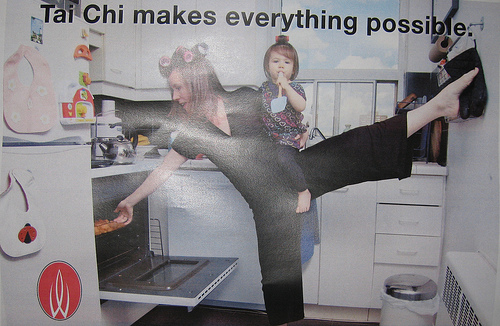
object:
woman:
[113, 42, 478, 326]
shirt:
[170, 87, 318, 213]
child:
[257, 36, 312, 213]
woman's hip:
[245, 150, 319, 209]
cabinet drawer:
[376, 174, 445, 205]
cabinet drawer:
[373, 202, 443, 237]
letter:
[40, 4, 56, 23]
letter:
[53, 9, 66, 23]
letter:
[69, 4, 74, 22]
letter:
[83, 4, 101, 24]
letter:
[103, 5, 116, 23]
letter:
[133, 10, 154, 24]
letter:
[157, 10, 171, 24]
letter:
[173, 5, 186, 24]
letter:
[188, 10, 201, 25]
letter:
[204, 10, 216, 25]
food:
[93, 216, 124, 236]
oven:
[92, 169, 238, 307]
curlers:
[159, 42, 208, 67]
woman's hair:
[158, 41, 228, 124]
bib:
[1, 45, 58, 133]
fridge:
[1, 0, 104, 326]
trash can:
[376, 274, 438, 326]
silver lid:
[384, 273, 438, 301]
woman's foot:
[430, 68, 478, 118]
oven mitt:
[445, 47, 489, 120]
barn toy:
[62, 87, 96, 118]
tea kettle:
[99, 135, 137, 165]